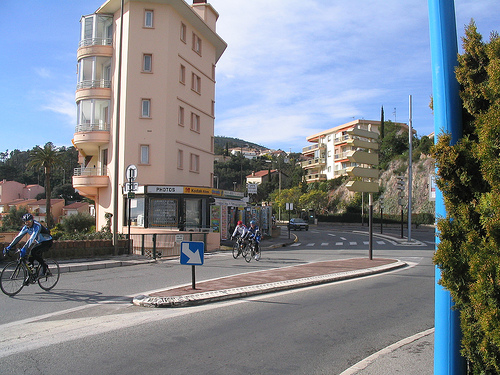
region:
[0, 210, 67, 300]
Person riding a bike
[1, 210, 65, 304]
Man wears a helmet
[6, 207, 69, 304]
Man wears blue and black cloths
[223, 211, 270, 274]
Two people riding bikes side by side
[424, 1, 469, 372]
Blue pole on right side of street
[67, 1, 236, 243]
Building has five floors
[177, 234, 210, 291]
Street sign has blue background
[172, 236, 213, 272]
Arrow of sign is white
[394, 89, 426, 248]
Pole is gray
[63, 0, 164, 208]
Building has balcony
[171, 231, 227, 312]
blue and white sign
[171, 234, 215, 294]
blue sign with white arrow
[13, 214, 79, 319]
person on bicycle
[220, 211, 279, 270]
two people on bicycle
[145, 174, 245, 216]
white and yellow signs with black lettering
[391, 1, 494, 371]
blue pole in photograph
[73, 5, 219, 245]
beige building with many stories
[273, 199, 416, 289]
street with white paint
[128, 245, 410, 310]
sidewalk dividing street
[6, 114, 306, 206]
mountain in background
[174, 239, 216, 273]
Blue and white sign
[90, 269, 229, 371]
Gray paved road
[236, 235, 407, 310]
Gray and brown paved sidewalk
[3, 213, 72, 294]
Man on a bike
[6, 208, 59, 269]
Man with a blue shirt on a bike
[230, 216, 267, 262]
Two people riding bikes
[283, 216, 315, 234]
Car driving on a road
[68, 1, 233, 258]
Tall building in a city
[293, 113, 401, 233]
Tan and orange building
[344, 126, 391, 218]
Arrow signs on a road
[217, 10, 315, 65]
Clouds are white color.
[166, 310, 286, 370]
Road is grey color.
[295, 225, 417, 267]
White lines in road.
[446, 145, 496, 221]
Leaves are green color.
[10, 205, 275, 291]
Three person are riding the cycle.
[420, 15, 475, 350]
Pole is blue color.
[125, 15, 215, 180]
Windows are attached to the wall.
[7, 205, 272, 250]
Three people are wearing helmet.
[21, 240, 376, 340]
Shadow falls on road.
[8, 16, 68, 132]
Sky is blue color.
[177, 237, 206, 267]
A BLUE AND WHITE SIGN WITH AN ARROW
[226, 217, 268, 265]
TWO PEOPLE BICYCLING SIDE BY SIDE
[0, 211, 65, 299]
A MAN WEARING BLACK AND BLUE ON A BICYCLE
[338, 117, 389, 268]
A POST WITH FIVE SIGNS ON IT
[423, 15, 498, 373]
AN EVERGREEN TREE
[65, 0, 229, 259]
A PEACH COLORED BUILDING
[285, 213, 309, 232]
A GRAY FOUR DOOR CAR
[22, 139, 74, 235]
A TALL PALM TREE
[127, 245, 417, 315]
A MEDIAN IN THE STREET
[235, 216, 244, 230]
A RED BICYCLE HELMET